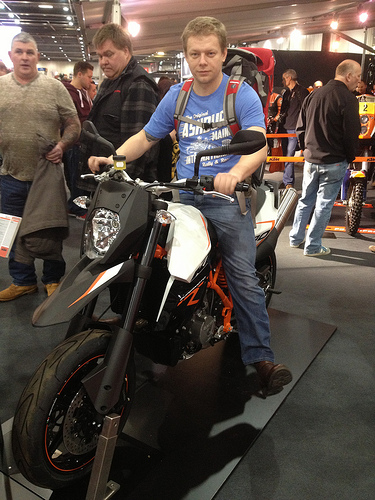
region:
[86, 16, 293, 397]
man sitting on motorcycle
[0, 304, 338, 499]
silver and black stand holding up motorcycle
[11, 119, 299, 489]
motorcycle is orange and black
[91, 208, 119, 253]
light on front of motorcycle is off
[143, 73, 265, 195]
man wearing blue shirt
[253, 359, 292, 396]
man wearing brown boot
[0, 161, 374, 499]
carpet is grey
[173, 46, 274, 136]
man wearing red backpack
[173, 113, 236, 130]
grey strap on backpack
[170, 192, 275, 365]
man wearing blue jeans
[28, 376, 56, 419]
tire made of rubber.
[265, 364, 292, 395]
boot on man's foot.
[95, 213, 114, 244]
headlight on the motorcycle.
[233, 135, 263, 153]
mirror on the motorcycle.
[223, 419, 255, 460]
shadow on the floor.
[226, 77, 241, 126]
backpack strap on man's shoulder.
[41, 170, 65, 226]
coat in man's hand.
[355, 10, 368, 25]
light near the ceiling.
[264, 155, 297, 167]
orange tape surrounding exhibit.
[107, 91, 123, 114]
black vest on man.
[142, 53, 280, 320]
The man is on a mortorcycle.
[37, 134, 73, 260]
The man has a coat in his hand.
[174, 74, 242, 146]
The straps of a backpack on man shoulders.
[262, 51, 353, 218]
People standing around.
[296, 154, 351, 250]
The man is wearing blue jeans.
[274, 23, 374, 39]
Lights on the ceiling.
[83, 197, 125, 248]
headlight in front of motorcycle.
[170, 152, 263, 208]
man hands on handles of motorcycles.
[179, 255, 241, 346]
The motorcycle have orange bars.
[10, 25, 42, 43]
The man has gray hair.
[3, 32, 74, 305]
man holding brown jacket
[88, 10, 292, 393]
man wearing blue t-shirt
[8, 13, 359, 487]
man sitting on motorcycle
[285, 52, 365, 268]
man wearing black coat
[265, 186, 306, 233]
stainless steel exhaust pipe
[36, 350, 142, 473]
orange trim around wheel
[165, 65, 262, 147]
red and grey backpack straps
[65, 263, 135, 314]
white and orange fender sticker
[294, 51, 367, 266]
man wearing light colored blue jeans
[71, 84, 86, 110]
white string on hoodie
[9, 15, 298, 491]
man sitting on a motorcycle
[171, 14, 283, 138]
man witha red and gray bookbag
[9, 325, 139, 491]
tire on the front of a motorcycle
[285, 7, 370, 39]
light illuminating the building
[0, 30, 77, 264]
man with tatoos holding his coat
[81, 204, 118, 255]
light on front of motorcycle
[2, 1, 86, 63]
rows of lights on the ceiling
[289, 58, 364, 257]
man looking at some something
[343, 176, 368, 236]
tire on a dirt bike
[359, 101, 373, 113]
black 2 on a yellow background